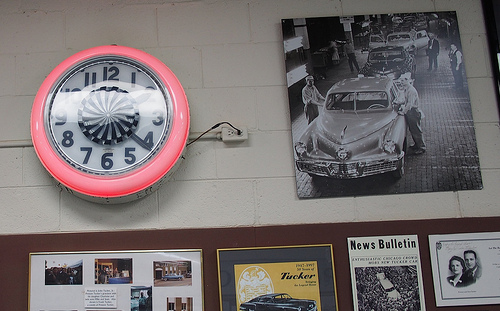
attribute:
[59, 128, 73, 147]
number — black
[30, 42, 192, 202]
neon — pink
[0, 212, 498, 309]
wall — brown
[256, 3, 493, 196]
photograph — black, white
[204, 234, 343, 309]
frame — gold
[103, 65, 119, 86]
number — black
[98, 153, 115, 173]
number — black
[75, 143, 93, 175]
number — black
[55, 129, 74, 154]
number — black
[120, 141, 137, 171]
number — black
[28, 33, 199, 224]
clock — red, black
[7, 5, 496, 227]
wall — tan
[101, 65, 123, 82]
number — black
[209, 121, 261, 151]
outlet — white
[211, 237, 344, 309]
photo — blue, yellow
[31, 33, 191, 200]
clock — red, black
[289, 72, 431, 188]
car — old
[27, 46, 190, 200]
clock — red, black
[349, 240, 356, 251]
letter — black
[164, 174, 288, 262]
block — white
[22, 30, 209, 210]
clock — black, red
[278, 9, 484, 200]
poster — black, white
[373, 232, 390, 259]
letter — black